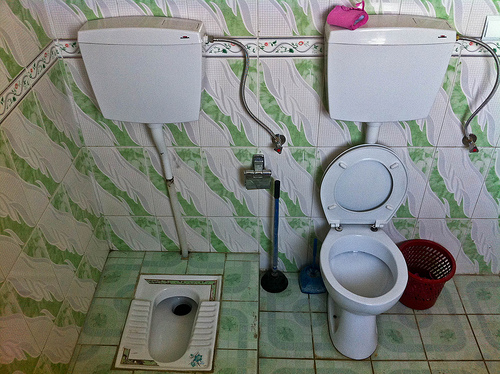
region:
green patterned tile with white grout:
[27, 113, 129, 238]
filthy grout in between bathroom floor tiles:
[241, 306, 321, 372]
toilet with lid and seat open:
[307, 134, 414, 365]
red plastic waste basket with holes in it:
[391, 220, 466, 331]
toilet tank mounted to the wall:
[308, 1, 478, 164]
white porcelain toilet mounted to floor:
[308, 137, 410, 364]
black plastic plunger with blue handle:
[255, 177, 290, 319]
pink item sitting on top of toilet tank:
[318, 1, 378, 46]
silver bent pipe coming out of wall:
[213, 31, 290, 156]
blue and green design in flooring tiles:
[463, 281, 498, 357]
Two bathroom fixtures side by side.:
[82, 12, 457, 371]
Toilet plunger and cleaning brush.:
[261, 179, 323, 298]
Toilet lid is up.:
[318, 142, 409, 227]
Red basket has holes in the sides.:
[395, 236, 457, 315]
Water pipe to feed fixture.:
[456, 33, 498, 153]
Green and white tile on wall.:
[0, 0, 499, 372]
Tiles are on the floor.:
[69, 247, 496, 370]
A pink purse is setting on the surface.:
[325, 0, 366, 32]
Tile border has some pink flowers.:
[1, 37, 498, 121]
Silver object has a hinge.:
[243, 154, 275, 263]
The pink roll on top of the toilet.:
[325, 5, 383, 26]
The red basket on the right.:
[394, 224, 454, 314]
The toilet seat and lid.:
[325, 139, 400, 224]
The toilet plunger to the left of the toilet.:
[262, 175, 287, 292]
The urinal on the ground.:
[127, 262, 214, 372]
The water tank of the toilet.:
[332, 17, 454, 128]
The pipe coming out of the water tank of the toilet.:
[450, 28, 492, 155]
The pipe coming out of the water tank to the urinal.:
[204, 17, 294, 155]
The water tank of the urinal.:
[73, 8, 215, 133]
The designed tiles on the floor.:
[90, 230, 496, 372]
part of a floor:
[271, 323, 312, 355]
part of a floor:
[276, 331, 291, 368]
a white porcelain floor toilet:
[113, 270, 222, 367]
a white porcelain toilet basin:
[317, 224, 410, 361]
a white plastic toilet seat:
[317, 143, 409, 230]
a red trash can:
[398, 236, 457, 312]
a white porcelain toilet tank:
[320, 13, 455, 124]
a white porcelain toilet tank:
[74, 18, 202, 124]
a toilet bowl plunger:
[260, 180, 290, 295]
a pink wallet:
[324, 2, 366, 27]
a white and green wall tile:
[75, 150, 150, 214]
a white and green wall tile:
[15, 182, 90, 298]